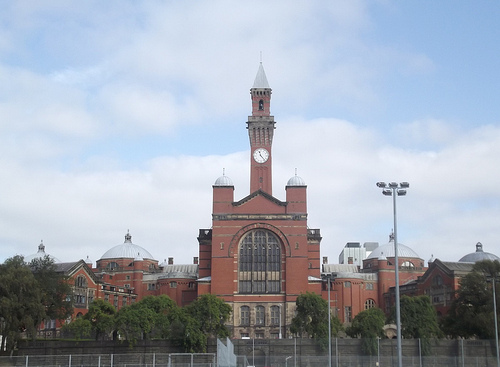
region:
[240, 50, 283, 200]
The building has a tower.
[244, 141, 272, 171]
The tower has a clock.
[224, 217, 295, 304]
The building has a large window.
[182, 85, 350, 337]
The building is red.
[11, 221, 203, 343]
Other building are in the background.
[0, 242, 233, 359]
Trees are in front of the buildings.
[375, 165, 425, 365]
A light is in front of the buildings.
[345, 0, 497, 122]
The sky is blue.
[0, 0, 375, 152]
The sky is partly cloudy.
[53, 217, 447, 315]
The buildings are made of brick.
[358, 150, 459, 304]
Lights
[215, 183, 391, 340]
Brick building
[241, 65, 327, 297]
Large clock tower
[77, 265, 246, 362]
Chain link fence in front of large brick building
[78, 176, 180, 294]
A dome roof on the brick building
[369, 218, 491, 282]
More domes on the brick building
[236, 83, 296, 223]
A large tower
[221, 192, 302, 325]
Windows on the building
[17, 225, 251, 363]
Lots of trees in front of the large brick building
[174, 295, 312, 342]
Front of the building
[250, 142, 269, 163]
Clock on tower.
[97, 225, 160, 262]
Dome on brick building.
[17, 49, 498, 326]
Church is made of brick.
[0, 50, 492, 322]
Building is made of brick.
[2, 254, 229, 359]
Trees in front of building.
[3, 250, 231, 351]
Trees in front of building are green.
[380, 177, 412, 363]
Lights on pole.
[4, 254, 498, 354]
Many trees in front of building.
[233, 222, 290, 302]
Curved window in front of building.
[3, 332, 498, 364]
Fence in front of building.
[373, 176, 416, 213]
five lights on pole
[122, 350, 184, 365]
chain link fence in foreground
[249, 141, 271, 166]
white faced clock on tower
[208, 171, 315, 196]
two white domes on building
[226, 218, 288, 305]
arched window on front of building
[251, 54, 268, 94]
steeple on top of tower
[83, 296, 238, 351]
green trees behind wall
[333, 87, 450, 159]
white clouds in daytime sky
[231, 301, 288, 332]
three tall parallel windows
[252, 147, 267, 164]
hands on clock face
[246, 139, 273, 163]
this is a clock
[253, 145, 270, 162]
these are clock hands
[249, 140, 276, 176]
these are numbers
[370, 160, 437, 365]
this is a light pole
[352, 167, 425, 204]
these are bright lights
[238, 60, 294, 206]
this is a clock tower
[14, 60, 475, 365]
this is a building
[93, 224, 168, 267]
this is a round roof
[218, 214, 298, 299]
this is a round large window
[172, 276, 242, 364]
this is a tree